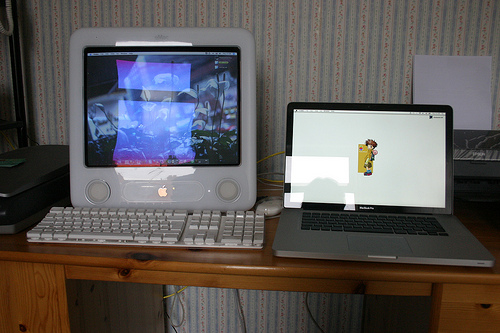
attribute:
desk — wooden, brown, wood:
[7, 236, 496, 332]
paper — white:
[417, 48, 493, 122]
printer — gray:
[421, 138, 493, 207]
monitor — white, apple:
[86, 28, 247, 206]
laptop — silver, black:
[272, 102, 493, 269]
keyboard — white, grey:
[34, 203, 271, 260]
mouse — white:
[257, 182, 288, 219]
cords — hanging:
[136, 286, 266, 322]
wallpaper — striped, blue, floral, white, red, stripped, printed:
[13, 10, 500, 123]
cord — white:
[262, 159, 285, 198]